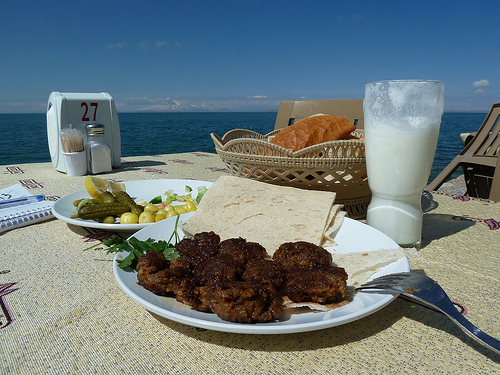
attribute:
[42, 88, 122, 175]
holder — numbered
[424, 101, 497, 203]
chair — tan, plastic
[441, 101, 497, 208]
chair — brown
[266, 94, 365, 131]
chair — brown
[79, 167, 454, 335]
plate — white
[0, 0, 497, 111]
sky — clear, blue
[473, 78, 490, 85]
cloud — few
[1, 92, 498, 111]
cloud — few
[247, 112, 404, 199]
basket — tan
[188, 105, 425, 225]
basket — tan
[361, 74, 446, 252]
glass — tall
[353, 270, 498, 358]
fork — upside down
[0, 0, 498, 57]
water — clear, blue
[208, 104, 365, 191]
basket — woven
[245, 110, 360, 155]
laof — brown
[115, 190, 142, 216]
pickle — small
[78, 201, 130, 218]
pickle — small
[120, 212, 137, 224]
bean — yellow 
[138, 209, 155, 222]
bean — yellow 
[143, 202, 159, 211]
bean — yellow 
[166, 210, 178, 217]
bean — yellow 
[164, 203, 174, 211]
bean — yellow 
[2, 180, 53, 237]
notebook — spiral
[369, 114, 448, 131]
liquid — white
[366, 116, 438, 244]
drink — frothy, white